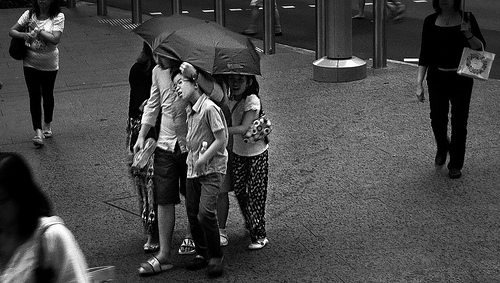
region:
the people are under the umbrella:
[125, 16, 297, 281]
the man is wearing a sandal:
[125, 250, 177, 280]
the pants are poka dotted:
[238, 153, 278, 229]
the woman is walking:
[10, 10, 93, 149]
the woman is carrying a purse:
[7, 15, 42, 60]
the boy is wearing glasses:
[170, 79, 196, 90]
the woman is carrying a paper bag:
[417, 13, 494, 189]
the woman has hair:
[10, 167, 41, 207]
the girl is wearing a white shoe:
[249, 238, 274, 252]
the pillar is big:
[311, 7, 373, 82]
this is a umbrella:
[158, 20, 251, 61]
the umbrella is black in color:
[176, 23, 220, 48]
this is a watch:
[188, 70, 202, 84]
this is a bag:
[453, 45, 495, 82]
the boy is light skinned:
[179, 84, 191, 93]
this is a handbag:
[6, 37, 26, 52]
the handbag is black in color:
[11, 39, 21, 49]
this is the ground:
[299, 147, 386, 251]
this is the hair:
[16, 160, 46, 205]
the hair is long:
[31, 180, 57, 207]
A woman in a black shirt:
[408, 0, 488, 173]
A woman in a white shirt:
[9, 0, 86, 144]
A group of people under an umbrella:
[116, 38, 301, 281]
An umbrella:
[130, 7, 264, 82]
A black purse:
[6, 8, 33, 60]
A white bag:
[457, 29, 494, 85]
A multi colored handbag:
[238, 93, 274, 147]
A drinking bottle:
[196, 138, 209, 170]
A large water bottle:
[128, 137, 155, 174]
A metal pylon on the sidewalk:
[363, 0, 393, 68]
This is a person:
[412, 0, 499, 181]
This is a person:
[224, 54, 283, 256]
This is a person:
[170, 70, 227, 279]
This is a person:
[138, 39, 182, 277]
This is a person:
[7, 2, 70, 149]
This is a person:
[0, 145, 105, 280]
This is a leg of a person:
[137, 147, 179, 277]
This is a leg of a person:
[248, 150, 273, 257]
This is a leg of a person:
[446, 78, 481, 190]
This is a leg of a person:
[426, 78, 451, 178]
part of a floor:
[341, 105, 396, 177]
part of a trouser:
[233, 169, 275, 236]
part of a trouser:
[198, 180, 219, 210]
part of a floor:
[308, 149, 363, 228]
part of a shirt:
[192, 110, 211, 134]